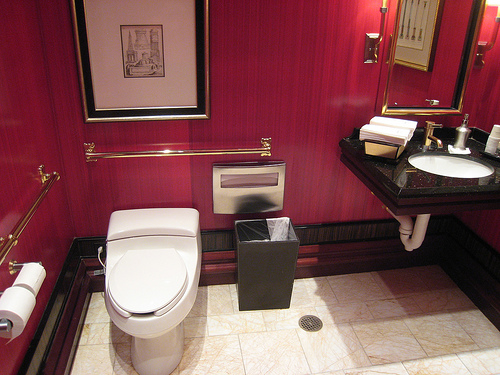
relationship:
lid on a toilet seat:
[83, 224, 203, 304] [102, 268, 182, 375]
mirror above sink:
[374, 1, 485, 119] [409, 151, 494, 178]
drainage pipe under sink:
[381, 202, 433, 251] [404, 141, 465, 249]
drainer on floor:
[299, 312, 324, 331] [70, 260, 494, 372]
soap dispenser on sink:
[472, 149, 494, 224] [349, 131, 462, 280]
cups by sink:
[461, 114, 498, 159] [419, 139, 479, 225]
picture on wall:
[69, 4, 206, 126] [37, 6, 444, 236]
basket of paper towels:
[367, 142, 397, 163] [353, 104, 412, 175]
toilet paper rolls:
[180, 267, 278, 375] [9, 281, 40, 375]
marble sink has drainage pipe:
[335, 122, 498, 215] [381, 202, 433, 251]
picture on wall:
[69, 4, 206, 126] [211, 10, 278, 95]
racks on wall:
[113, 144, 210, 165] [217, 70, 274, 150]